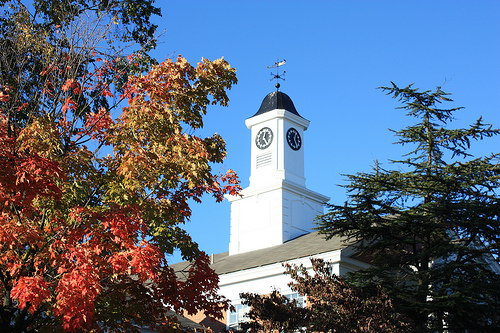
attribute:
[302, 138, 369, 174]
clouds — white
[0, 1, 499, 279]
sky — blue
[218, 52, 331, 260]
tower — white, a clock tower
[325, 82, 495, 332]
tree — green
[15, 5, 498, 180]
sky — clear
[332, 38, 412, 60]
sky — blue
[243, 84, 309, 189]
steeple — black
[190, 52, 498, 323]
tiles — black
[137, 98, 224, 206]
light leaves — some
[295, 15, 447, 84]
sky — dark blue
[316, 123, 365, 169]
clouds — white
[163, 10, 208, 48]
sky — blue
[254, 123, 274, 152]
clock — black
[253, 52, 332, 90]
spire — metal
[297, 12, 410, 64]
sky — blue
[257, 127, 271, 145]
clock hand — white 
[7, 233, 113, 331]
leaves — red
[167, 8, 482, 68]
sky — blue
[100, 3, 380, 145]
wind — directional wind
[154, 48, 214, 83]
cloud — white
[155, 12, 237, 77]
clouds — white